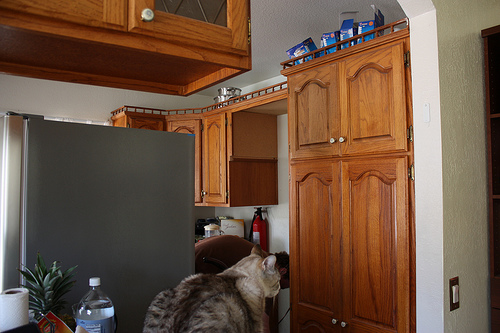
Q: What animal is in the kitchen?
A: A grey cat.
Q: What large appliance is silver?
A: The refrigerator.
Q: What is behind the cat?
A: A water bottle.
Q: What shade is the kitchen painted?
A: White.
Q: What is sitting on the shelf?
A: Silver bowls.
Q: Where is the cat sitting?
A: On the counter/.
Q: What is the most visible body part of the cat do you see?
A: Backside.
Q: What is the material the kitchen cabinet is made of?
A: Wood.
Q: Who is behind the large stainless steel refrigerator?
A: Lady.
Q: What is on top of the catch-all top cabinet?
A: Boxes.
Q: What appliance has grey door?
A: Fridge.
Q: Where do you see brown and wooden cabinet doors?
A: Kitchen.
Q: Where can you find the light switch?
A: White wall.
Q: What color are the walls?
A: White.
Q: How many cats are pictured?
A: 1.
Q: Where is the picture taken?
A: Kitchen.